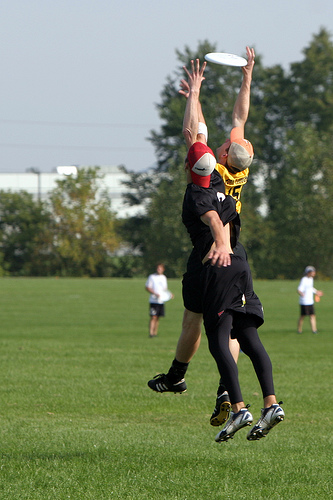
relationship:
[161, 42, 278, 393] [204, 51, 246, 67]
two men jumping for frisbee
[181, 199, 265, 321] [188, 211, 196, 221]
sweater seen part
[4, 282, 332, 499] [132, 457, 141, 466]
grass seen part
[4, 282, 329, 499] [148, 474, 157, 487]
grass seen part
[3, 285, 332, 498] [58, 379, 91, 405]
ground seen part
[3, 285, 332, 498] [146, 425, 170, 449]
ground seen part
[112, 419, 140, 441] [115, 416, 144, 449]
ground seen part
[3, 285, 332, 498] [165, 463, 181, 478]
ground seen part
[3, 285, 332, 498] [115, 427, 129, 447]
ground seen part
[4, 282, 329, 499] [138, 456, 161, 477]
grass seen part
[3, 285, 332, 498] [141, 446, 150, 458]
ground seen part